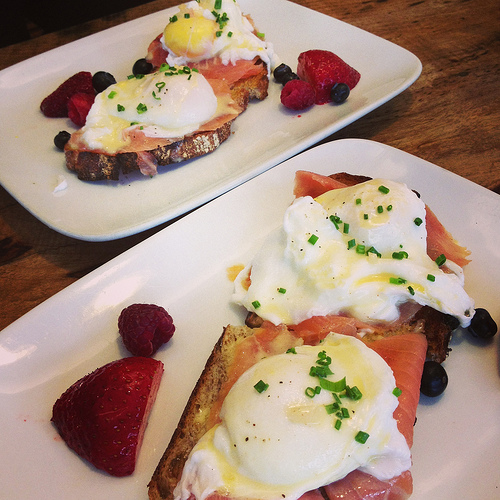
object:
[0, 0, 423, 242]
plate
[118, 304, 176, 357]
raspberry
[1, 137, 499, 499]
plate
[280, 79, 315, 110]
raspberry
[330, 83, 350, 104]
blueberry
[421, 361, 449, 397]
blueberry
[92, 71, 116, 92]
blueberry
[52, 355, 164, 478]
strawberry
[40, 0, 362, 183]
food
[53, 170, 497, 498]
food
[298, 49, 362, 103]
strawberry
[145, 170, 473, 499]
sandwich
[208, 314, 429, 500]
fish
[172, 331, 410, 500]
egg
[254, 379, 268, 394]
chive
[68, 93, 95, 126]
raspberry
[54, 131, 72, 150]
blueberry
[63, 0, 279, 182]
sandwich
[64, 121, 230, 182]
crust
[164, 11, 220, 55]
yolk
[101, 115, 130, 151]
yolk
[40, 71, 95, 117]
strawberry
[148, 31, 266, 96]
salmon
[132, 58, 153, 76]
blueberry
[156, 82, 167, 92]
chive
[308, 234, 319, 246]
chive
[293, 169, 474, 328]
salmon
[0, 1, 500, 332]
table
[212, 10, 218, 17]
chive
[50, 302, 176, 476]
fruit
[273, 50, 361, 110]
fruit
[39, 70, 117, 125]
fruit